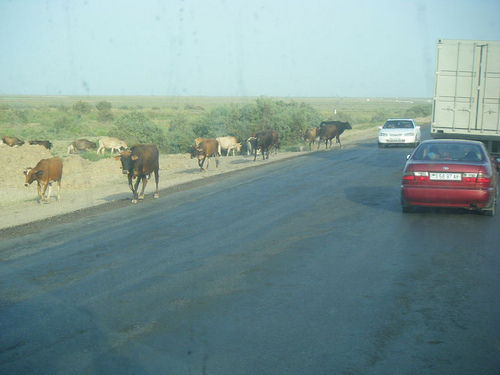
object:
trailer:
[428, 37, 498, 141]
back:
[401, 142, 489, 208]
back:
[431, 38, 499, 137]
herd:
[0, 118, 354, 207]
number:
[426, 169, 462, 183]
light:
[414, 171, 431, 181]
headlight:
[378, 131, 388, 138]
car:
[395, 130, 498, 219]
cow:
[95, 135, 127, 157]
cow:
[215, 135, 241, 155]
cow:
[247, 127, 282, 163]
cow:
[313, 116, 355, 152]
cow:
[17, 153, 69, 206]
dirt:
[0, 147, 23, 225]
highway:
[0, 117, 499, 372]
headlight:
[402, 128, 420, 138]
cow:
[188, 133, 222, 172]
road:
[0, 141, 500, 375]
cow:
[117, 142, 162, 204]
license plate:
[429, 171, 462, 181]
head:
[18, 164, 43, 189]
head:
[118, 147, 139, 177]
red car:
[396, 134, 499, 217]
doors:
[436, 35, 500, 135]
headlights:
[401, 173, 417, 183]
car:
[374, 112, 424, 150]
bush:
[105, 111, 168, 144]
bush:
[93, 99, 117, 124]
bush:
[166, 109, 211, 138]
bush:
[167, 103, 217, 138]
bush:
[189, 92, 322, 132]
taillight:
[402, 169, 430, 182]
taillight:
[458, 167, 484, 181]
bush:
[159, 134, 192, 153]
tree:
[406, 97, 432, 115]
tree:
[150, 104, 161, 110]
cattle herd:
[2, 97, 358, 211]